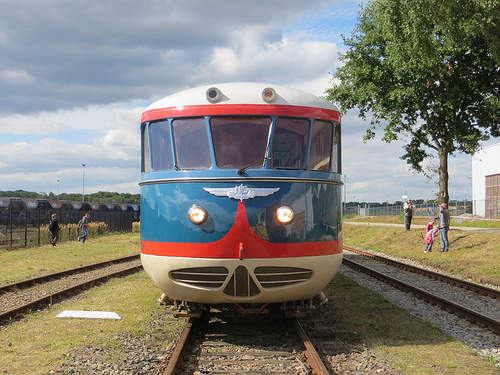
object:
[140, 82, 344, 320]
train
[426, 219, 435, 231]
people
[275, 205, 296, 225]
lights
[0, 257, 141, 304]
tracks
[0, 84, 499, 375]
train area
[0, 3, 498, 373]
day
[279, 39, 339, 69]
clouds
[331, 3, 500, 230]
tree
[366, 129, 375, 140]
leaves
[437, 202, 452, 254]
mom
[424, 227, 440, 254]
daughter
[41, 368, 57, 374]
rocks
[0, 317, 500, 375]
grass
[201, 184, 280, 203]
logo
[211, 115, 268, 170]
windows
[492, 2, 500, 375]
right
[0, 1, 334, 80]
sky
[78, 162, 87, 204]
post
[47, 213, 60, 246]
boy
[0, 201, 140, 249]
fence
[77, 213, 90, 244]
boy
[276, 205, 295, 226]
right headlight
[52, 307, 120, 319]
wood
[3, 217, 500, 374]
ground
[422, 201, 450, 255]
mom and daughter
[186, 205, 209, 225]
headlight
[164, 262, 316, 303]
design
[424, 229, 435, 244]
jacket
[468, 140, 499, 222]
building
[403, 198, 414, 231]
man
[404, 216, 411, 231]
pants